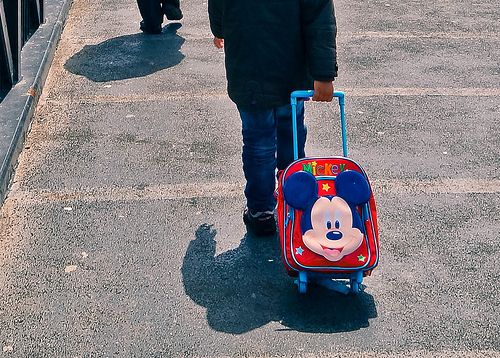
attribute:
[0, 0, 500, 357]
pavement — gray, grey, concrete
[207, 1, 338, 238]
person — walking, pulling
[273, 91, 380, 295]
backpack — rolling, mickey mouse, blue, red, carry all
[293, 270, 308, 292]
wheel — blue, aqua blue, light blue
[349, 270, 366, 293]
wheel — blue, aqua blue, light blue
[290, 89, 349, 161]
handle — blue, aqua blue, light blue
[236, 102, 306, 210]
pants — blue, wrinkled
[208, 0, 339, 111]
jacket — blue, down, black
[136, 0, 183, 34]
man — walking, in background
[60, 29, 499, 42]
line — white, faint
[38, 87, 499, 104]
line — white, faint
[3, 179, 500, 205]
line — white, faint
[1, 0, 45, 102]
fence — iron, black, metal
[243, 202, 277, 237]
sneaker — black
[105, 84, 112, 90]
spot — small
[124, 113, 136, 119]
spot — small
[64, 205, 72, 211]
spot — small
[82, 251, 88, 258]
spot — small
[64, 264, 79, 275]
spot — small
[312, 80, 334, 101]
hand — man's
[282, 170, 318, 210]
ear — large, blue, big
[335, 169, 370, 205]
ear — large, blue, big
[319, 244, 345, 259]
grin — large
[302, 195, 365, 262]
face — mickey mouse's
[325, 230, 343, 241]
nose — shiny, black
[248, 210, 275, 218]
edge — white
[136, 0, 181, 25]
pants — black